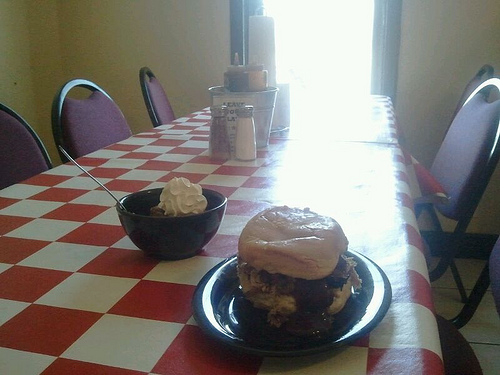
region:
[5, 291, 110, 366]
Small red checkered patten on a table cloth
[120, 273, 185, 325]
Small red checkered patten on a table cloth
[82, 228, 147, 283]
Small red checkered patten on a table cloth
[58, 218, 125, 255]
Small red checkered patten on a table cloth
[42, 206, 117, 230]
Small red checkered patten on a table cloth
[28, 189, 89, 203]
Small red checkered patten on a table cloth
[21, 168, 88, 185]
Small red checkered patten on a table cloth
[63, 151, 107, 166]
Small red checkered patten on a table cloth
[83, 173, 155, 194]
Small red checkered patten on a table cloth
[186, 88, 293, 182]
salt and pepper shakers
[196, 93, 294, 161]
salt and pepper shakers on a table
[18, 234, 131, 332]
a red and white table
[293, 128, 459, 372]
a table with a red and white table cloth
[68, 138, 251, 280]
a black bowl with whipped cream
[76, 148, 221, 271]
whipped cream in a black bowl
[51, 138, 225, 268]
a black bowl on a table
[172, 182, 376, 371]
a black plate of food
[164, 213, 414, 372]
a black plate on a table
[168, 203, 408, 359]
big sandwich on a plate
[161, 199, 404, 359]
flavorful sandwich on a plate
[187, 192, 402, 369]
delicious sandwich on a plate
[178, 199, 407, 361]
hearty sandwich on a plate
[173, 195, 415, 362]
nice sandwich on a plate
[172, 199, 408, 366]
great sandwich on a plate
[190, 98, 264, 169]
spices on a table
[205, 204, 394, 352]
sandwich on a small plate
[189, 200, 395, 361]
A burger on a plate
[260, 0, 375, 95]
Daylight coming from a window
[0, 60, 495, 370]
Chairs around a long table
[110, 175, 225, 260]
A bowl of ice cream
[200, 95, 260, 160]
A salt and pepper shaker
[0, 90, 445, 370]
Red and white checkered tablecloth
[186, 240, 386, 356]
The plate is black and round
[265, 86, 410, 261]
Light glare is on the table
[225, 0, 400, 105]
Curtains on both sides of the window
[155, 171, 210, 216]
The whipped cream is white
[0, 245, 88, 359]
Red blocks make up the table.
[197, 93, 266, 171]
Salt and pepper shakers on the table.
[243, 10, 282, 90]
Roll of paper towels on the table.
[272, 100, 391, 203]
Sunlight shining on the table.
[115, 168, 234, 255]
Bowl of food on the table.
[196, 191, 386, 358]
Plate of food on the table.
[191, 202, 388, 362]
Sandwich on a blue plate.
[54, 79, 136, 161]
Red chair at the table.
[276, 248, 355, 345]
Sauce dripping from the sandwich.